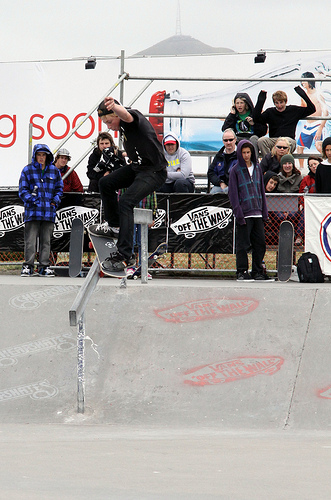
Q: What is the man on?
A: The man is on the skateboard.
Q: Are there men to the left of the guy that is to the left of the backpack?
A: Yes, there is a man to the left of the guy.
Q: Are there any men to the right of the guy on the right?
A: No, the man is to the left of the guy.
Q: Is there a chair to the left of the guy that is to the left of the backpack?
A: No, there is a man to the left of the guy.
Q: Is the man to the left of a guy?
A: Yes, the man is to the left of a guy.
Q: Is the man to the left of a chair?
A: No, the man is to the left of a guy.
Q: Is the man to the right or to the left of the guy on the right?
A: The man is to the left of the guy.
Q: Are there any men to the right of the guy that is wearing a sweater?
A: Yes, there is a man to the right of the guy.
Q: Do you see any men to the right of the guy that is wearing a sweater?
A: Yes, there is a man to the right of the guy.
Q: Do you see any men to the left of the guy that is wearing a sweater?
A: No, the man is to the right of the guy.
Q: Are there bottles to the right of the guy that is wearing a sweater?
A: No, there is a man to the right of the guy.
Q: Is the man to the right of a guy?
A: Yes, the man is to the right of a guy.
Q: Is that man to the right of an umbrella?
A: No, the man is to the right of a guy.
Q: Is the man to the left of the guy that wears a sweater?
A: No, the man is to the right of the guy.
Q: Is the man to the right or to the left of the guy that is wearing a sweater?
A: The man is to the right of the guy.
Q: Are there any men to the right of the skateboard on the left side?
A: Yes, there is a man to the right of the skateboard.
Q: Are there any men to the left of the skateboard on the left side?
A: No, the man is to the right of the skateboard.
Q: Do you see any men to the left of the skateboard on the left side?
A: No, the man is to the right of the skateboard.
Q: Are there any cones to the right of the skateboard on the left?
A: No, there is a man to the right of the skateboard.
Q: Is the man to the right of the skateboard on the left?
A: Yes, the man is to the right of the skateboard.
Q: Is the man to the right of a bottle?
A: No, the man is to the right of the skateboard.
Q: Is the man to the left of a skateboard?
A: No, the man is to the right of a skateboard.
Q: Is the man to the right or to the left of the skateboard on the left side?
A: The man is to the right of the skateboard.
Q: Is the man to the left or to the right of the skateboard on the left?
A: The man is to the right of the skateboard.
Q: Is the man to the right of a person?
A: No, the man is to the left of a person.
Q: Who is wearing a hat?
A: The man is wearing a hat.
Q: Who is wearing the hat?
A: The man is wearing a hat.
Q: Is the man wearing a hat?
A: Yes, the man is wearing a hat.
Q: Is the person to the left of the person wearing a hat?
A: Yes, the man is wearing a hat.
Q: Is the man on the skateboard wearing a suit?
A: No, the man is wearing a hat.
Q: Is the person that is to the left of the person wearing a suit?
A: No, the man is wearing a hat.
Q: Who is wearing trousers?
A: The man is wearing trousers.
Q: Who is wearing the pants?
A: The man is wearing trousers.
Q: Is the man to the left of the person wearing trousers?
A: Yes, the man is wearing trousers.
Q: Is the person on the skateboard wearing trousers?
A: Yes, the man is wearing trousers.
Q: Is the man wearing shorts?
A: No, the man is wearing trousers.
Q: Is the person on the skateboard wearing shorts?
A: No, the man is wearing trousers.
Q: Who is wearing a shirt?
A: The man is wearing a shirt.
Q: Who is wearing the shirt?
A: The man is wearing a shirt.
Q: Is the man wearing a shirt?
A: Yes, the man is wearing a shirt.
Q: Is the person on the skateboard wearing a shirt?
A: Yes, the man is wearing a shirt.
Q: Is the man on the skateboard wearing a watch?
A: No, the man is wearing a shirt.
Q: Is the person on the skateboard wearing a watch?
A: No, the man is wearing a shirt.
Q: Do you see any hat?
A: Yes, there is a hat.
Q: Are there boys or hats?
A: Yes, there is a hat.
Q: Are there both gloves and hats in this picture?
A: No, there is a hat but no gloves.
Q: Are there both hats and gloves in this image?
A: No, there is a hat but no gloves.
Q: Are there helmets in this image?
A: No, there are no helmets.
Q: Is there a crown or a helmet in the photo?
A: No, there are no helmets or crowns.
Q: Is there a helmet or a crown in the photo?
A: No, there are no helmets or crowns.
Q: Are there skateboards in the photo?
A: Yes, there is a skateboard.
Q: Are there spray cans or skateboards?
A: Yes, there is a skateboard.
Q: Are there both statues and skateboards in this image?
A: No, there is a skateboard but no statues.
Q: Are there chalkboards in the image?
A: No, there are no chalkboards.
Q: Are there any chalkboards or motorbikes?
A: No, there are no chalkboards or motorbikes.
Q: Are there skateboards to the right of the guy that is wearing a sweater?
A: Yes, there is a skateboard to the right of the guy.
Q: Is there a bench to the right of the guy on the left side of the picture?
A: No, there is a skateboard to the right of the guy.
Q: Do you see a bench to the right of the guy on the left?
A: No, there is a skateboard to the right of the guy.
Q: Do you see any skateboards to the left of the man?
A: Yes, there is a skateboard to the left of the man.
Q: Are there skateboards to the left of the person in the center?
A: Yes, there is a skateboard to the left of the man.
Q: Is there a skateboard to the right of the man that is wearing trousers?
A: No, the skateboard is to the left of the man.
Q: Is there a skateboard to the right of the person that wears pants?
A: No, the skateboard is to the left of the man.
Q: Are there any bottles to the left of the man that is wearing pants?
A: No, there is a skateboard to the left of the man.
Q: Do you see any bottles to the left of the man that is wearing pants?
A: No, there is a skateboard to the left of the man.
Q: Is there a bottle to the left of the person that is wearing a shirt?
A: No, there is a skateboard to the left of the man.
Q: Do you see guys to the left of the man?
A: Yes, there is a guy to the left of the man.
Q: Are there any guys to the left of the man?
A: Yes, there is a guy to the left of the man.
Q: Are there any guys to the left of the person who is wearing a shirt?
A: Yes, there is a guy to the left of the man.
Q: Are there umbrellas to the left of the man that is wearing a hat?
A: No, there is a guy to the left of the man.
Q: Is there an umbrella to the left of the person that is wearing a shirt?
A: No, there is a guy to the left of the man.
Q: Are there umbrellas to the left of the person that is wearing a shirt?
A: No, there is a guy to the left of the man.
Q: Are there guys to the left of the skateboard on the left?
A: Yes, there is a guy to the left of the skateboard.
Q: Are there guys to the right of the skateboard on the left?
A: No, the guy is to the left of the skateboard.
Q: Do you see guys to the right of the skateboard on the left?
A: No, the guy is to the left of the skateboard.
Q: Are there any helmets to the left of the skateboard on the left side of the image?
A: No, there is a guy to the left of the skateboard.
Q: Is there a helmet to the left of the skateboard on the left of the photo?
A: No, there is a guy to the left of the skateboard.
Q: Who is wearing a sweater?
A: The guy is wearing a sweater.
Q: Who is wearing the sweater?
A: The guy is wearing a sweater.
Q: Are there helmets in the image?
A: No, there are no helmets.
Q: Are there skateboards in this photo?
A: Yes, there is a skateboard.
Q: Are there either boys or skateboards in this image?
A: Yes, there is a skateboard.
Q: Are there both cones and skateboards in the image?
A: No, there is a skateboard but no cones.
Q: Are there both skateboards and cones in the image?
A: No, there is a skateboard but no cones.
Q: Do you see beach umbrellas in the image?
A: No, there are no beach umbrellas.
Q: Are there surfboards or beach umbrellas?
A: No, there are no beach umbrellas or surfboards.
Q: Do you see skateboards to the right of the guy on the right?
A: Yes, there is a skateboard to the right of the guy.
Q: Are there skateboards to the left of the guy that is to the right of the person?
A: No, the skateboard is to the right of the guy.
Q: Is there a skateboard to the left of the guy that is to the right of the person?
A: No, the skateboard is to the right of the guy.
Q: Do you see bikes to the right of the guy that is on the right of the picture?
A: No, there is a skateboard to the right of the guy.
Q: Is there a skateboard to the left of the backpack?
A: Yes, there is a skateboard to the left of the backpack.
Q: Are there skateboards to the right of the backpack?
A: No, the skateboard is to the left of the backpack.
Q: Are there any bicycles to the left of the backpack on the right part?
A: No, there is a skateboard to the left of the backpack.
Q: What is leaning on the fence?
A: The skateboard is leaning on the fence.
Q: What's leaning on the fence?
A: The skateboard is leaning on the fence.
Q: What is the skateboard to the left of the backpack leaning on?
A: The skateboard is leaning on the fence.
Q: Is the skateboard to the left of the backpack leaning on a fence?
A: Yes, the skateboard is leaning on a fence.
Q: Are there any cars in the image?
A: No, there are no cars.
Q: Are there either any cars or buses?
A: No, there are no cars or buses.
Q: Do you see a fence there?
A: Yes, there is a fence.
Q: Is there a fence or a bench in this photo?
A: Yes, there is a fence.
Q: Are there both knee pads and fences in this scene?
A: No, there is a fence but no knee pads.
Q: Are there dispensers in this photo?
A: No, there are no dispensers.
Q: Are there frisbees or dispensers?
A: No, there are no dispensers or frisbees.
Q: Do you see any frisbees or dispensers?
A: No, there are no dispensers or frisbees.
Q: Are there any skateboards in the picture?
A: Yes, there is a skateboard.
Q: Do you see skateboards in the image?
A: Yes, there is a skateboard.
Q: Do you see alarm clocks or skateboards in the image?
A: Yes, there is a skateboard.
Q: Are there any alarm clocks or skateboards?
A: Yes, there is a skateboard.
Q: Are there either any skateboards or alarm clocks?
A: Yes, there is a skateboard.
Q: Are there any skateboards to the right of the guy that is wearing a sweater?
A: Yes, there is a skateboard to the right of the guy.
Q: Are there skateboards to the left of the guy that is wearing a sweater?
A: No, the skateboard is to the right of the guy.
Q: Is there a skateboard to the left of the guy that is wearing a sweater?
A: No, the skateboard is to the right of the guy.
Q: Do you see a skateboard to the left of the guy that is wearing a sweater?
A: No, the skateboard is to the right of the guy.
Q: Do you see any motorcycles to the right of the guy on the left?
A: No, there is a skateboard to the right of the guy.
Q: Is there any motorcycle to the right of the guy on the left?
A: No, there is a skateboard to the right of the guy.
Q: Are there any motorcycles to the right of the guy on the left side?
A: No, there is a skateboard to the right of the guy.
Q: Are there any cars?
A: No, there are no cars.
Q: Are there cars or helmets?
A: No, there are no cars or helmets.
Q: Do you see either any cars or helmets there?
A: No, there are no cars or helmets.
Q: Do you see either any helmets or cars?
A: No, there are no cars or helmets.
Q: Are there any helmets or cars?
A: No, there are no cars or helmets.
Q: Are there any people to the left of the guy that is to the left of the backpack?
A: Yes, there is a person to the left of the guy.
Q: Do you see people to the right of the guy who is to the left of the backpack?
A: No, the person is to the left of the guy.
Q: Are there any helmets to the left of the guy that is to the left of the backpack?
A: No, there is a person to the left of the guy.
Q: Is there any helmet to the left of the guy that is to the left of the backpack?
A: No, there is a person to the left of the guy.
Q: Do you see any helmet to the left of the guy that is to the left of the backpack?
A: No, there is a person to the left of the guy.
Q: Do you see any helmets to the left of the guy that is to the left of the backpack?
A: No, there is a person to the left of the guy.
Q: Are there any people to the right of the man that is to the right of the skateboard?
A: Yes, there is a person to the right of the man.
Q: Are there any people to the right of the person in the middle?
A: Yes, there is a person to the right of the man.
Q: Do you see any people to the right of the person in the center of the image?
A: Yes, there is a person to the right of the man.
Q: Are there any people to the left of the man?
A: No, the person is to the right of the man.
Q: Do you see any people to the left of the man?
A: No, the person is to the right of the man.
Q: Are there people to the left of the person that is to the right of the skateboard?
A: No, the person is to the right of the man.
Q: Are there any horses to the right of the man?
A: No, there is a person to the right of the man.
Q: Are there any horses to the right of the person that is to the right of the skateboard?
A: No, there is a person to the right of the man.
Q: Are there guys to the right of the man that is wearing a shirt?
A: Yes, there is a guy to the right of the man.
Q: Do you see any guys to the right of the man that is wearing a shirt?
A: Yes, there is a guy to the right of the man.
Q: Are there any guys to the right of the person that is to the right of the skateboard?
A: Yes, there is a guy to the right of the man.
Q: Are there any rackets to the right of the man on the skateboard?
A: No, there is a guy to the right of the man.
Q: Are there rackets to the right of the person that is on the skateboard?
A: No, there is a guy to the right of the man.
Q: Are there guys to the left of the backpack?
A: Yes, there is a guy to the left of the backpack.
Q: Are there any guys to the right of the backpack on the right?
A: No, the guy is to the left of the backpack.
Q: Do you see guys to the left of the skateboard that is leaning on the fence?
A: Yes, there is a guy to the left of the skateboard.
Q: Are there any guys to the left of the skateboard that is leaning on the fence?
A: Yes, there is a guy to the left of the skateboard.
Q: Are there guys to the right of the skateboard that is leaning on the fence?
A: No, the guy is to the left of the skateboard.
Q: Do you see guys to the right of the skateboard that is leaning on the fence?
A: No, the guy is to the left of the skateboard.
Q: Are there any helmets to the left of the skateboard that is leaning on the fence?
A: No, there is a guy to the left of the skateboard.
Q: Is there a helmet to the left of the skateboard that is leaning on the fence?
A: No, there is a guy to the left of the skateboard.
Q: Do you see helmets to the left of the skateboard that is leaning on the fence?
A: No, there is a guy to the left of the skateboard.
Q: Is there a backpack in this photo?
A: Yes, there is a backpack.